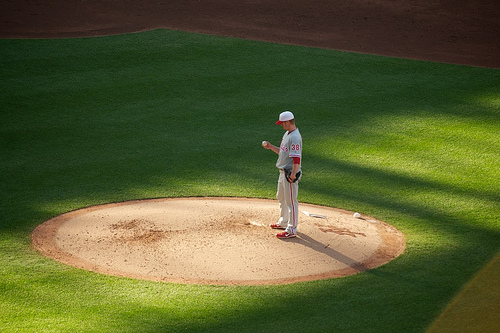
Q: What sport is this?
A: Baseball.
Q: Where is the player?
A: Baseball field.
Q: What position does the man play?
A: Pitcher.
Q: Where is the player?
A: Pitcher mound.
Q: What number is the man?
A: 38.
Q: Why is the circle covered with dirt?
A: Pitcher's mound.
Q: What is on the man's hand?
A: Baseball mitt.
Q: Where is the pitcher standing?
A: Mound.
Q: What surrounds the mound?
A: Grass.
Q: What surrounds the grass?
A: Dirt.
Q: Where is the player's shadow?
A: Behind him.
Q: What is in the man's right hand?
A: Baseball.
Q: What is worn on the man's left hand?
A: Glove.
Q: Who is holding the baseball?
A: The pitcher.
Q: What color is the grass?
A: Green.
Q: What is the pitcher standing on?
A: The mound.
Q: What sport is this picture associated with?
A: Baseball.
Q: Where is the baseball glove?
A: On his hand.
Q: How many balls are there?
A: Two.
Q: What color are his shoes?
A: Red.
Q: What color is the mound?
A: Brown.